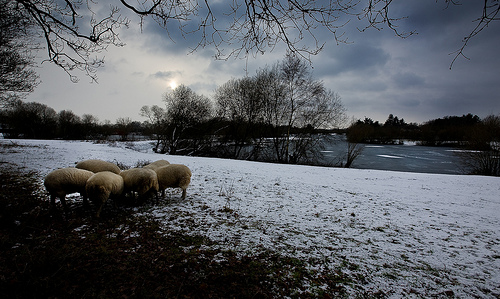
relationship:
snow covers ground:
[3, 136, 499, 297] [1, 139, 500, 298]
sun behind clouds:
[162, 75, 181, 94] [108, 10, 264, 87]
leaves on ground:
[1, 171, 285, 296] [1, 139, 500, 298]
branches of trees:
[12, 2, 498, 81] [142, 61, 355, 167]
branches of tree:
[12, 2, 498, 81] [1, 2, 35, 153]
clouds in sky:
[108, 10, 264, 87] [0, 0, 498, 122]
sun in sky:
[162, 75, 181, 94] [0, 0, 498, 122]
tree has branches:
[1, 2, 35, 153] [12, 2, 498, 81]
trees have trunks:
[142, 61, 355, 167] [163, 139, 311, 163]